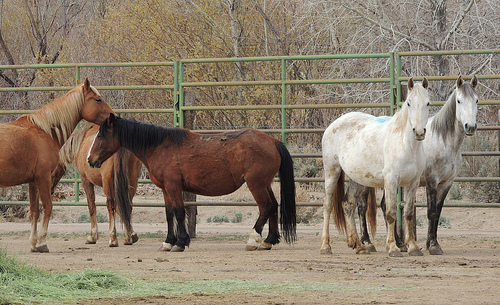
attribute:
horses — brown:
[0, 75, 298, 253]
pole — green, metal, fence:
[182, 57, 282, 60]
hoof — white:
[244, 228, 262, 251]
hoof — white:
[254, 238, 273, 249]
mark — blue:
[371, 115, 391, 123]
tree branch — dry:
[187, 0, 230, 35]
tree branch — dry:
[203, 17, 235, 55]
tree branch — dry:
[197, 37, 233, 55]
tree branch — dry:
[163, 30, 195, 78]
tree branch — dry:
[141, 20, 171, 45]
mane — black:
[96, 112, 188, 153]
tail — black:
[274, 137, 298, 244]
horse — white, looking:
[359, 74, 480, 256]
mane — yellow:
[15, 80, 85, 146]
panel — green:
[0, 58, 178, 208]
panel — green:
[177, 50, 402, 243]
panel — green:
[395, 46, 485, 243]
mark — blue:
[377, 114, 390, 124]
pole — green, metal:
[179, 104, 285, 112]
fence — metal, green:
[6, 51, 497, 229]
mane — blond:
[17, 81, 109, 150]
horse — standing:
[349, 74, 479, 248]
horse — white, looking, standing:
[322, 77, 431, 256]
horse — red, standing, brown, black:
[88, 111, 298, 251]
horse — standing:
[64, 117, 140, 246]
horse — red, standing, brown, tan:
[0, 76, 115, 251]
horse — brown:
[58, 117, 138, 248]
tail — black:
[278, 142, 298, 245]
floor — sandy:
[4, 231, 498, 302]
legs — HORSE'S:
[139, 175, 192, 245]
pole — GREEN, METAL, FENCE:
[257, 53, 297, 103]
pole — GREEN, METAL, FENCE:
[175, 46, 225, 97]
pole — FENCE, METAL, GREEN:
[256, 45, 313, 81]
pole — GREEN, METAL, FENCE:
[276, 48, 348, 77]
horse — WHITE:
[315, 78, 440, 261]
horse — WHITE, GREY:
[320, 87, 430, 251]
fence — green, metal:
[2, 39, 498, 213]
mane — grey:
[432, 90, 459, 146]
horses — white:
[312, 69, 483, 260]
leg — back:
[314, 141, 343, 262]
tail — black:
[272, 131, 306, 240]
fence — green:
[4, 56, 493, 243]